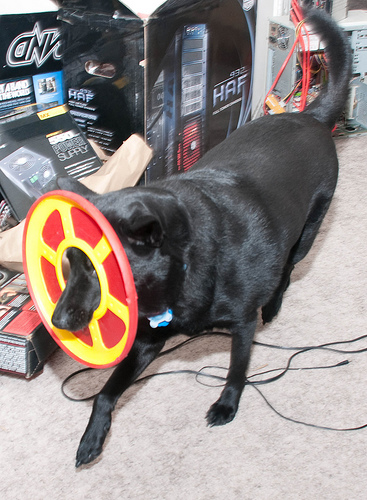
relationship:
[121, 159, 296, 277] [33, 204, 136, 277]
dog has frisbee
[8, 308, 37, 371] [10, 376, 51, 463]
box on floor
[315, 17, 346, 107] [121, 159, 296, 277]
tail of dog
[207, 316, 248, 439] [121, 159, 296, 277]
leg of dog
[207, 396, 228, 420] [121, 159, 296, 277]
paw of dog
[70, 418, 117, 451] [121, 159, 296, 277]
paw of dog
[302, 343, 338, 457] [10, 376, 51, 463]
wire on floor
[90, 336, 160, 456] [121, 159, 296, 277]
leg of dog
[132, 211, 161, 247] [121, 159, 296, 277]
ear of dog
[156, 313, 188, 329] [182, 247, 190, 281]
tag on collar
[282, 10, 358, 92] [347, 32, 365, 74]
tower with no case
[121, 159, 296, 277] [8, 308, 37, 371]
dog by box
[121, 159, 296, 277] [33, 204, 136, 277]
dog with frisbee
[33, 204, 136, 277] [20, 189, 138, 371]
frisbee has a frisbee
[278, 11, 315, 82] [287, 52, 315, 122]
box for cords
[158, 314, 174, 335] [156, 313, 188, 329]
silver on tag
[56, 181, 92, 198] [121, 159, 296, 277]
ear of dog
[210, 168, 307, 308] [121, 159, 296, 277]
side of dog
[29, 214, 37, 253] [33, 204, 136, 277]
yellow on frisbee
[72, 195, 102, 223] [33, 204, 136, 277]
red of frisbee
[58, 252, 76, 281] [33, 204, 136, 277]
middle of frisbee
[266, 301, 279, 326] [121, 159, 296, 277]
paw of dog